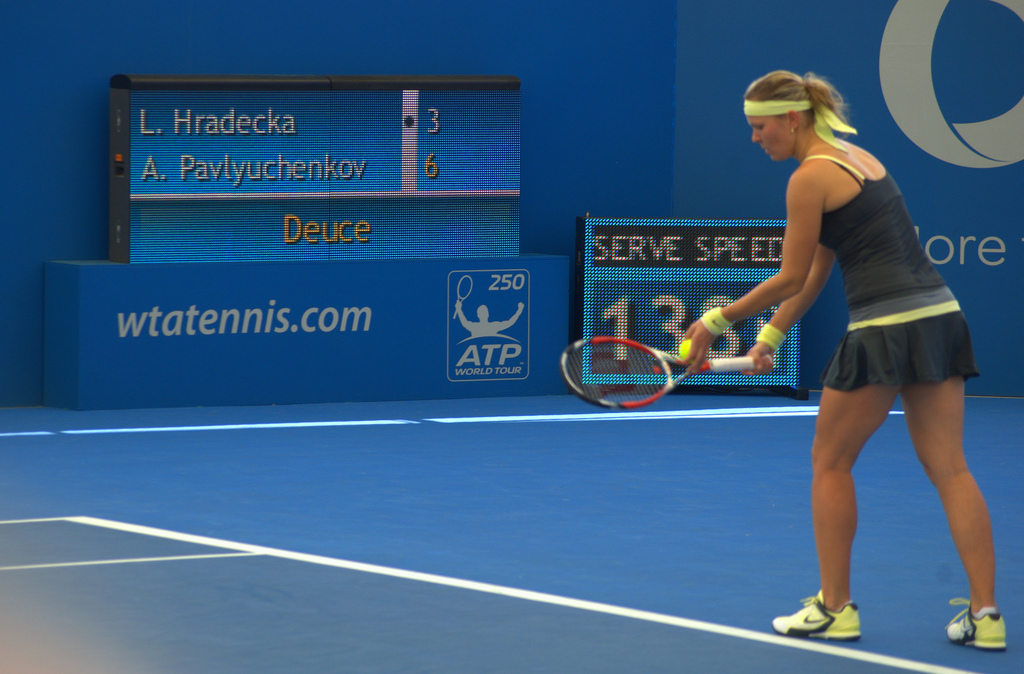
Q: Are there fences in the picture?
A: No, there are no fences.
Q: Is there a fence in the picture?
A: No, there are no fences.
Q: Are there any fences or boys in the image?
A: No, there are no fences or boys.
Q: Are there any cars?
A: No, there are no cars.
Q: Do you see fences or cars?
A: No, there are no cars or fences.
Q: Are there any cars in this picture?
A: No, there are no cars.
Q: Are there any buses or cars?
A: No, there are no cars or buses.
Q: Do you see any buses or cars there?
A: No, there are no cars or buses.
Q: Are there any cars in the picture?
A: No, there are no cars.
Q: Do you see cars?
A: No, there are no cars.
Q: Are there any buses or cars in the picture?
A: No, there are no cars or buses.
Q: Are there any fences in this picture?
A: No, there are no fences.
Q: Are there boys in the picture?
A: No, there are no boys.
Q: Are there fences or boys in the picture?
A: No, there are no boys or fences.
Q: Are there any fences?
A: No, there are no fences.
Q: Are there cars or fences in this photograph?
A: No, there are no fences or cars.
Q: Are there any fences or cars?
A: No, there are no fences or cars.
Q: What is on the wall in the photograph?
A: The sign is on the wall.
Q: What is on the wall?
A: The sign is on the wall.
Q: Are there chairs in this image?
A: No, there are no chairs.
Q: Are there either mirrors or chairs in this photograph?
A: No, there are no chairs or mirrors.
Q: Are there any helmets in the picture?
A: No, there are no helmets.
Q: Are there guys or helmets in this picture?
A: No, there are no helmets or guys.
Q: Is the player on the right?
A: Yes, the player is on the right of the image.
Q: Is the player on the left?
A: No, the player is on the right of the image.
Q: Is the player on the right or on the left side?
A: The player is on the right of the image.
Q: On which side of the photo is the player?
A: The player is on the right of the image.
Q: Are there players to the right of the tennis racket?
A: Yes, there is a player to the right of the tennis racket.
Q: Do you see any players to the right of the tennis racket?
A: Yes, there is a player to the right of the tennis racket.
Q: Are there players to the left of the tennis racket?
A: No, the player is to the right of the tennis racket.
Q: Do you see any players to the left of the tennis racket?
A: No, the player is to the right of the tennis racket.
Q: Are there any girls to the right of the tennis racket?
A: No, there is a player to the right of the tennis racket.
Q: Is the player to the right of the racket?
A: Yes, the player is to the right of the racket.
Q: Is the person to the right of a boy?
A: No, the player is to the right of the racket.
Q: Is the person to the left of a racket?
A: No, the player is to the right of a racket.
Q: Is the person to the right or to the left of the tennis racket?
A: The player is to the right of the tennis racket.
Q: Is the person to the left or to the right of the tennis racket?
A: The player is to the right of the tennis racket.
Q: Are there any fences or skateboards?
A: No, there are no fences or skateboards.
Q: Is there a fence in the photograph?
A: No, there are no fences.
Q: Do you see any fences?
A: No, there are no fences.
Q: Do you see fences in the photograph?
A: No, there are no fences.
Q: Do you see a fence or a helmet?
A: No, there are no fences or helmets.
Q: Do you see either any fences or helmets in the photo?
A: No, there are no fences or helmets.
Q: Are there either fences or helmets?
A: No, there are no fences or helmets.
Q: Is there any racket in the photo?
A: Yes, there is a racket.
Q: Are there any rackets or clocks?
A: Yes, there is a racket.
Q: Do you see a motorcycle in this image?
A: No, there are no motorcycles.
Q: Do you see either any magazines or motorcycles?
A: No, there are no motorcycles or magazines.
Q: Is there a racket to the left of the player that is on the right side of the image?
A: Yes, there is a racket to the left of the player.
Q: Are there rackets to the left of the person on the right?
A: Yes, there is a racket to the left of the player.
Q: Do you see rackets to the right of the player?
A: No, the racket is to the left of the player.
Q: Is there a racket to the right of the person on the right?
A: No, the racket is to the left of the player.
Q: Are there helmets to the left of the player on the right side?
A: No, there is a racket to the left of the player.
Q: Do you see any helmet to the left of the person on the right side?
A: No, there is a racket to the left of the player.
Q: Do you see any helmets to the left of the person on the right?
A: No, there is a racket to the left of the player.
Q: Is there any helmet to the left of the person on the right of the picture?
A: No, there is a racket to the left of the player.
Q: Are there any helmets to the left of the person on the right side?
A: No, there is a racket to the left of the player.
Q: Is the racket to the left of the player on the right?
A: Yes, the racket is to the left of the player.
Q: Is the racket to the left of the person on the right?
A: Yes, the racket is to the left of the player.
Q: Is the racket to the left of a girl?
A: No, the racket is to the left of the player.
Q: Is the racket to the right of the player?
A: No, the racket is to the left of the player.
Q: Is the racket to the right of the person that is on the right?
A: No, the racket is to the left of the player.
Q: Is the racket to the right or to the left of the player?
A: The racket is to the left of the player.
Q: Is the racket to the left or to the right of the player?
A: The racket is to the left of the player.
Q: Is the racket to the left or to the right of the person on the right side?
A: The racket is to the left of the player.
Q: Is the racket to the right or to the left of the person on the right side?
A: The racket is to the left of the player.